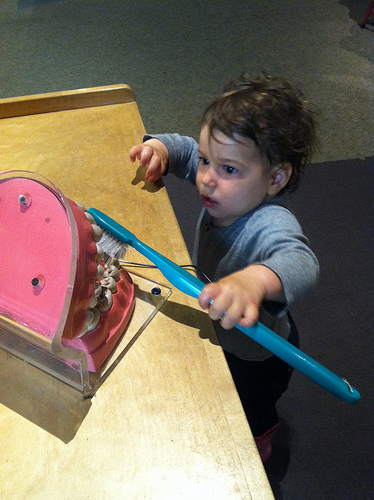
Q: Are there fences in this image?
A: No, there are no fences.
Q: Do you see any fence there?
A: No, there are no fences.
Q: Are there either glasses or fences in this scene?
A: No, there are no fences or glasses.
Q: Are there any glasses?
A: No, there are no glasses.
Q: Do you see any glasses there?
A: No, there are no glasses.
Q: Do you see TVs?
A: No, there are no tvs.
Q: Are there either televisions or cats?
A: No, there are no televisions or cats.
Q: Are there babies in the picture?
A: Yes, there is a baby.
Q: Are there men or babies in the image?
A: Yes, there is a baby.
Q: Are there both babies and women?
A: No, there is a baby but no women.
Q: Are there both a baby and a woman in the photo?
A: No, there is a baby but no women.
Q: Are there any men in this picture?
A: No, there are no men.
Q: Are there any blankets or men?
A: No, there are no men or blankets.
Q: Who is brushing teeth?
A: The baby is brushing teeth.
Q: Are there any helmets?
A: No, there are no helmets.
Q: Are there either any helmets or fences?
A: No, there are no helmets or fences.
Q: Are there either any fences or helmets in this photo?
A: No, there are no helmets or fences.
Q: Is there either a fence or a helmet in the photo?
A: No, there are no helmets or fences.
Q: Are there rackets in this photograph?
A: No, there are no rackets.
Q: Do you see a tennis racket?
A: No, there are no rackets.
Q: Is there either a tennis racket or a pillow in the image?
A: No, there are no rackets or pillows.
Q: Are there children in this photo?
A: Yes, there is a child.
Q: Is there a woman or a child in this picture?
A: Yes, there is a child.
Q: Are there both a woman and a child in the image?
A: No, there is a child but no women.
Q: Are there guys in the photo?
A: No, there are no guys.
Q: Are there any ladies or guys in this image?
A: No, there are no guys or ladies.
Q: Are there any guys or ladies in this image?
A: No, there are no guys or ladies.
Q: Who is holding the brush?
A: The child is holding the brush.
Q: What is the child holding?
A: The child is holding the brush.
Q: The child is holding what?
A: The child is holding the brush.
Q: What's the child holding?
A: The child is holding the brush.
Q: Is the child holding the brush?
A: Yes, the child is holding the brush.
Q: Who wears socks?
A: The kid wears socks.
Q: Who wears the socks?
A: The kid wears socks.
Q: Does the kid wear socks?
A: Yes, the kid wears socks.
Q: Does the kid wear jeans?
A: No, the kid wears socks.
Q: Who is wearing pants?
A: The kid is wearing pants.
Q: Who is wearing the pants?
A: The kid is wearing pants.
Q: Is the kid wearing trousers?
A: Yes, the kid is wearing trousers.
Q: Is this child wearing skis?
A: No, the child is wearing trousers.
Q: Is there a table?
A: Yes, there is a table.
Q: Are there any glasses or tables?
A: Yes, there is a table.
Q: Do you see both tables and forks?
A: No, there is a table but no forks.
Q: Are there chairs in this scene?
A: No, there are no chairs.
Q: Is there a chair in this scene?
A: No, there are no chairs.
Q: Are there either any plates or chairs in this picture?
A: No, there are no chairs or plates.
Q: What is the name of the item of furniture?
A: The piece of furniture is a table.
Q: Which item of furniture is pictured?
A: The piece of furniture is a table.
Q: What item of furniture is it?
A: The piece of furniture is a table.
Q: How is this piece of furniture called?
A: That is a table.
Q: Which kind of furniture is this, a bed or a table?
A: That is a table.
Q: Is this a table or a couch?
A: This is a table.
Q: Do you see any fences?
A: No, there are no fences.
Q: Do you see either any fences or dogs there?
A: No, there are no fences or dogs.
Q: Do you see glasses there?
A: No, there are no glasses.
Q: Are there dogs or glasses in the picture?
A: No, there are no glasses or dogs.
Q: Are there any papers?
A: No, there are no papers.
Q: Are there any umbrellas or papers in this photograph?
A: No, there are no papers or umbrellas.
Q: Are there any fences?
A: No, there are no fences.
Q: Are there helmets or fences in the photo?
A: No, there are no fences or helmets.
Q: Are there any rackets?
A: No, there are no rackets.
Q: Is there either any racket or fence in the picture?
A: No, there are no rackets or fences.